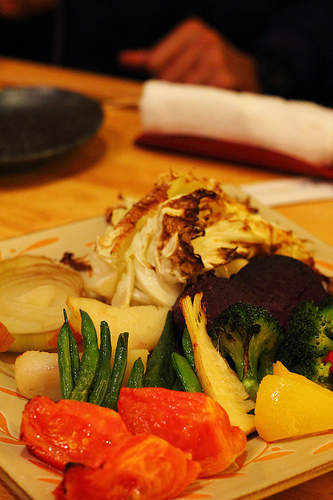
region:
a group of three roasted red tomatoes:
[21, 384, 244, 499]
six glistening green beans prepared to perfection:
[53, 306, 147, 405]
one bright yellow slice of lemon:
[254, 362, 332, 443]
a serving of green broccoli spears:
[217, 301, 332, 387]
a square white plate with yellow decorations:
[1, 180, 331, 499]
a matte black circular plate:
[0, 85, 103, 182]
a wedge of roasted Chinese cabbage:
[100, 167, 332, 303]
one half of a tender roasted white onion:
[2, 254, 79, 352]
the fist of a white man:
[116, 17, 254, 88]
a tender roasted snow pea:
[167, 351, 201, 391]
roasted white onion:
[0, 238, 105, 350]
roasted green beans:
[51, 304, 210, 407]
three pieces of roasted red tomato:
[11, 379, 273, 496]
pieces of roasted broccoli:
[209, 287, 331, 400]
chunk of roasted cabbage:
[76, 168, 321, 322]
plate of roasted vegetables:
[2, 208, 331, 498]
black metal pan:
[3, 77, 112, 184]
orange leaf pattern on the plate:
[235, 422, 314, 494]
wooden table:
[55, 155, 126, 205]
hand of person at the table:
[110, 9, 330, 121]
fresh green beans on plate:
[30, 314, 142, 385]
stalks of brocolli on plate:
[213, 298, 272, 372]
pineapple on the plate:
[186, 299, 266, 424]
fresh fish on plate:
[17, 385, 134, 456]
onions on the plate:
[10, 260, 125, 332]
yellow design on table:
[94, 159, 259, 197]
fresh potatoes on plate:
[111, 184, 295, 260]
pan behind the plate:
[0, 93, 147, 161]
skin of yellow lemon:
[241, 362, 326, 450]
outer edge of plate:
[242, 456, 330, 491]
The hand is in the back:
[96, 18, 254, 118]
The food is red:
[17, 402, 154, 497]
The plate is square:
[16, 200, 311, 488]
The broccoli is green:
[203, 310, 331, 395]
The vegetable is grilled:
[146, 198, 251, 299]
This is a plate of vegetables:
[6, 241, 313, 482]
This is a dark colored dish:
[2, 86, 113, 171]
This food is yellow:
[238, 371, 328, 444]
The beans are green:
[30, 311, 168, 395]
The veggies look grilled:
[14, 215, 322, 451]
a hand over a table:
[108, 13, 263, 103]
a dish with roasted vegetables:
[1, 158, 331, 493]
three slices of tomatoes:
[15, 380, 247, 496]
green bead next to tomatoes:
[48, 309, 190, 396]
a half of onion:
[0, 243, 75, 342]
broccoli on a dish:
[198, 255, 331, 389]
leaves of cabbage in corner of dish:
[73, 165, 314, 287]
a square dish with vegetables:
[3, 176, 331, 491]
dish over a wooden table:
[5, 72, 331, 495]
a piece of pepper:
[245, 356, 331, 448]